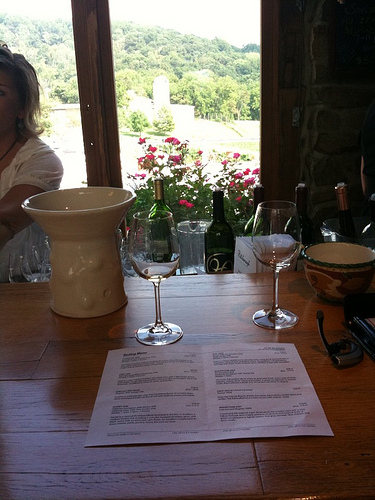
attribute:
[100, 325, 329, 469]
menu — white, restaurant menue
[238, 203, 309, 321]
wine glass — empty, clear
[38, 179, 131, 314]
vase — white, ceramic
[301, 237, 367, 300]
bowl — small, ceramic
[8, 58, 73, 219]
woman — sitting, standing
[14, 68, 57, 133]
hair — blonde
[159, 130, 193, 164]
rose — pink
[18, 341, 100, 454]
table — wood, wooden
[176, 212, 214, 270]
pitcher — empty